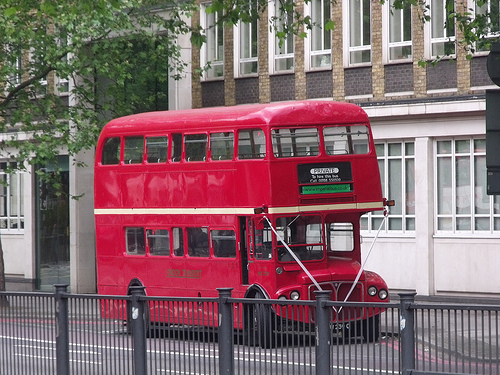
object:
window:
[125, 227, 146, 255]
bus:
[92, 102, 391, 344]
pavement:
[1, 293, 489, 355]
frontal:
[248, 103, 393, 346]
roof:
[98, 95, 368, 137]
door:
[245, 209, 273, 292]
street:
[4, 300, 500, 369]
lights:
[270, 282, 392, 310]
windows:
[211, 229, 235, 259]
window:
[270, 127, 319, 156]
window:
[275, 216, 322, 260]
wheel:
[126, 289, 148, 335]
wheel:
[251, 304, 275, 348]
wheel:
[363, 314, 381, 340]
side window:
[169, 222, 184, 256]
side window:
[183, 224, 213, 258]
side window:
[207, 224, 237, 259]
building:
[0, 0, 499, 309]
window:
[234, 126, 270, 155]